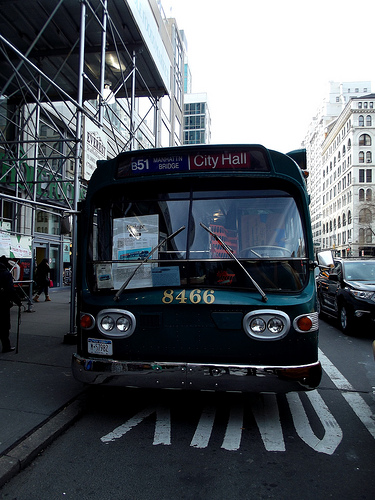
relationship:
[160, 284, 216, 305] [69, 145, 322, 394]
numbers on bus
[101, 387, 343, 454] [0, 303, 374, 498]
letters on road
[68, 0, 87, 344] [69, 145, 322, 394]
pole beside bus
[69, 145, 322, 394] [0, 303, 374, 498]
bus on road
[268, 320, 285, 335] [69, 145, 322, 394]
headlight on bus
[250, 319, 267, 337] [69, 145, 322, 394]
headlight on bus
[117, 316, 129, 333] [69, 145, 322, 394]
headlight on bus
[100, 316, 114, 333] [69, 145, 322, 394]
headlight on bus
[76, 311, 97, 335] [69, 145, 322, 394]
headlight on bus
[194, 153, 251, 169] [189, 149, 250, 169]
sign on sign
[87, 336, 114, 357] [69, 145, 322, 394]
plate on bus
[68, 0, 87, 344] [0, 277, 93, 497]
pole on sidewalk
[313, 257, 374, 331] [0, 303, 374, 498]
car driving on road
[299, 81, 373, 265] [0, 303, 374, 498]
building by road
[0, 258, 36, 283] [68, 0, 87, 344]
sign under pole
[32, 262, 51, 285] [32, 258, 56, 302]
coat on woman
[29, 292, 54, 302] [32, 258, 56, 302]
boots on woman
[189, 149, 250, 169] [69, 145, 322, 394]
sign on bus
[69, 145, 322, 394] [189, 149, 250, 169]
bus has sign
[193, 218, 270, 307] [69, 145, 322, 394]
wiper on bus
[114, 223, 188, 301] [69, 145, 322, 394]
wiper on bus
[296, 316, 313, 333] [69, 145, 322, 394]
headlight on bus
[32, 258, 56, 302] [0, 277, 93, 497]
woman on sidewalk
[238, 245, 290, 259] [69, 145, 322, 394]
wheel on bus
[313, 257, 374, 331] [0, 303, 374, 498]
car on road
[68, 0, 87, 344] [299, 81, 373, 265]
pole near building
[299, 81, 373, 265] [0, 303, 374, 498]
building on road